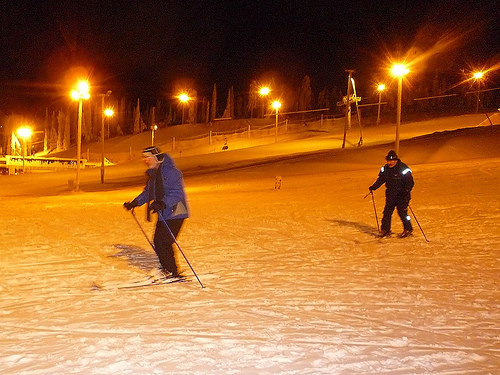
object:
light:
[82, 93, 93, 100]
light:
[178, 92, 189, 102]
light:
[387, 58, 409, 80]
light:
[259, 86, 271, 96]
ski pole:
[364, 187, 381, 233]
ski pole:
[408, 205, 430, 242]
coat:
[134, 154, 189, 220]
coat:
[372, 159, 415, 200]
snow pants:
[152, 218, 184, 276]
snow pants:
[380, 195, 413, 232]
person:
[368, 150, 415, 238]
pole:
[75, 98, 82, 191]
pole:
[182, 102, 184, 125]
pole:
[275, 109, 279, 142]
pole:
[393, 77, 402, 155]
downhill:
[0, 160, 499, 373]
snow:
[0, 157, 499, 374]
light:
[18, 127, 32, 138]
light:
[475, 73, 482, 79]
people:
[122, 146, 189, 283]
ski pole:
[156, 210, 206, 288]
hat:
[142, 144, 164, 163]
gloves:
[149, 199, 167, 213]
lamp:
[71, 92, 80, 101]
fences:
[248, 118, 289, 138]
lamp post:
[275, 108, 279, 141]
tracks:
[0, 321, 499, 354]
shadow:
[324, 213, 378, 236]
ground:
[0, 195, 499, 375]